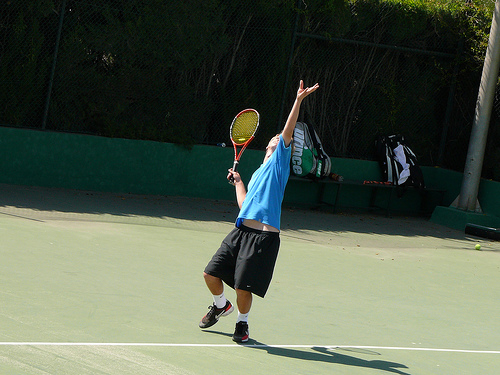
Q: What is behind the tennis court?
A: Trees.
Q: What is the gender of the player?
A: Male.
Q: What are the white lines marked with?
A: Chalk.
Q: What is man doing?
A: Playing tennis.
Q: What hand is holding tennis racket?
A: Right.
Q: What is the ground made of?
A: Concrete.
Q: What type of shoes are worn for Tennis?
A: Tennis shoes.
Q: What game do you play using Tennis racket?
A: Tennis.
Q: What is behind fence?
A: Trees.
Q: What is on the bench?
A: 2 backpacks.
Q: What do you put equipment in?
A: Bag.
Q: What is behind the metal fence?
A: Trees.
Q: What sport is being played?
A: Tennis.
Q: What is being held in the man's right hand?
A: A tennis racquet.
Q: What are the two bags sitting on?
A: A bench.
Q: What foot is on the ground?
A: The left.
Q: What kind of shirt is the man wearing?
A: A blue t-shirt.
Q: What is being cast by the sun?
A: Shadows.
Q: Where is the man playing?
A: On a tennis court.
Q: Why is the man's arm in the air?
A: He threw the ball up.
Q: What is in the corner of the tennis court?
A: A silver pole.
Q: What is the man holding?
A: A tennis racket.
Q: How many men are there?
A: One.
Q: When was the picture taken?
A: Daytime.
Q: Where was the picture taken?
A: A tennis court.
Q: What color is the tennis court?
A: Green.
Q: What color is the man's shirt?
A: Blue.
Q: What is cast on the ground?
A: Shadows.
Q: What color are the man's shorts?
A: Black.